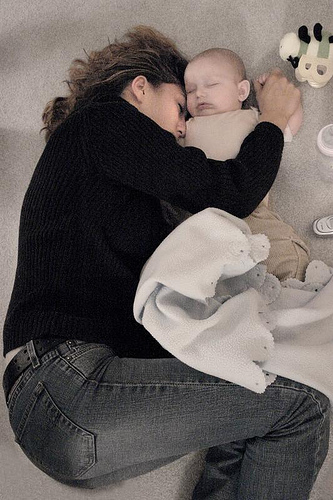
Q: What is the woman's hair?
A: A woman's brown hair.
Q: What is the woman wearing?
A: A woman's black shirt.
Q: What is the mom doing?
A: A mom sleeping with her baby.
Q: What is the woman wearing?
A: A woman in a black shirt.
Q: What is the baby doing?
A: A beautiful baby sleeping.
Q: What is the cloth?
A: The baby white cloth.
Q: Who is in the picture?
A: Mother and baby.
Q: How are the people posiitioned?
A: Laying down.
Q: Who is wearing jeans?
A: The woman.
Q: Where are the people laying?
A: The floor.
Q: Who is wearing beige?
A: The baby.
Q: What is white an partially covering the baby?
A: A blanket.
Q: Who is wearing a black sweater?
A: The woman.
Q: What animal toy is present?
A: A bee.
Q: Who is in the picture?
A: A woman and child.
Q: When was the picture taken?
A: While people were sleep.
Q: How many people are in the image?
A: Two.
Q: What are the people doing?
A: Sleeping.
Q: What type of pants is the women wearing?
A: Jeans.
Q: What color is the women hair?
A: Brown.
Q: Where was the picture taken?
A: On the bedroom floor.